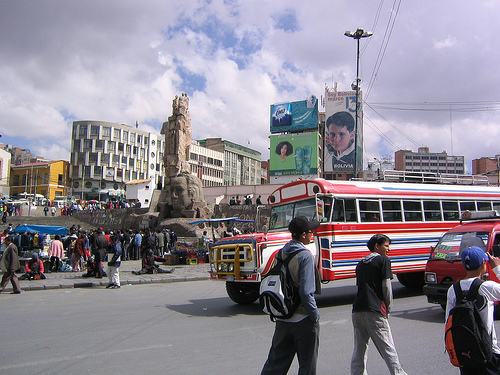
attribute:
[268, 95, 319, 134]
billboard — advertising, older, blue, white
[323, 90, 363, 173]
billboard — advertising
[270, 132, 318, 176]
billboard — advertising, green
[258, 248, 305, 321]
backpack — black, white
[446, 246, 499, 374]
boy — walking, young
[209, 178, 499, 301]
bus — red, striped, blue, white, colorful, large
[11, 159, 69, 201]
house — yellow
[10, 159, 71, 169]
roof — pink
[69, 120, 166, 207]
building — multi-story, rounded, white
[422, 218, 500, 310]
vehicle — red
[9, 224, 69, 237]
canopy — blue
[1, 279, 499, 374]
street — gray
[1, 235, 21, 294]
man — walking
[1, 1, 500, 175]
clouds — large, gray, fluffy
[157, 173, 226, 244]
bust — large, big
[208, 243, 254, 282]
grill — yellow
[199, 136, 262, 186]
building — green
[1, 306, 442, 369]
line — white, faint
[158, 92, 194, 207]
statue — large, tan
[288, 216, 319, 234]
cap — black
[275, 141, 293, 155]
hair — dark